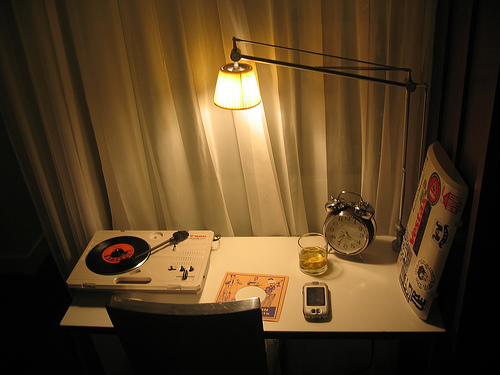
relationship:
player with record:
[64, 224, 218, 294] [81, 233, 153, 275]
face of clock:
[327, 215, 364, 252] [320, 189, 378, 257]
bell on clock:
[352, 192, 381, 217] [319, 200, 377, 260]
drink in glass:
[300, 252, 329, 272] [290, 231, 328, 273]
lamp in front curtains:
[213, 36, 429, 251] [1, 0, 499, 302]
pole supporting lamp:
[250, 39, 404, 251] [211, 77, 349, 147]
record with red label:
[82, 235, 150, 278] [108, 244, 130, 261]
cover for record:
[207, 271, 294, 325] [86, 210, 153, 295]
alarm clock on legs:
[319, 189, 378, 263] [328, 241, 368, 271]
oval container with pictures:
[396, 140, 476, 334] [397, 125, 462, 323]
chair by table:
[125, 175, 406, 342] [74, 225, 454, 339]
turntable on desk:
[63, 224, 233, 304] [55, 211, 462, 343]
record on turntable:
[82, 235, 150, 280] [76, 220, 212, 292]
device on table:
[303, 282, 332, 322] [55, 226, 453, 345]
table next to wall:
[61, 236, 448, 341] [5, 5, 492, 284]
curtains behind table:
[1, 0, 499, 300] [58, 236, 451, 374]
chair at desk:
[105, 296, 283, 374] [57, 231, 498, 371]